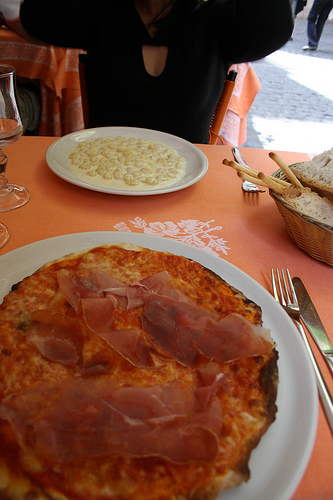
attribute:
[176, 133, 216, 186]
plate — white, round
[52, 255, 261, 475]
pizza — close, here, red, round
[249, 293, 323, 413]
bowl — white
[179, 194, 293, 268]
table — orange, brown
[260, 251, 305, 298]
fork — shiny, silver, here, metal, close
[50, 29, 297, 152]
chair — dark, brown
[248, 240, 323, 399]
fork — stainless, steel, one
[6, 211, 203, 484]
plate — white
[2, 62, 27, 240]
glass — empty, wine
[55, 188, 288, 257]
tablecloth — white, orange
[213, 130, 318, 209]
bread — products